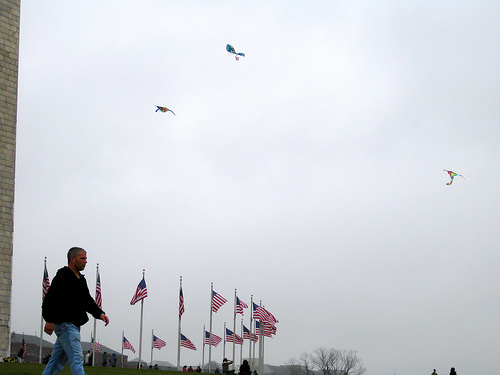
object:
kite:
[223, 42, 245, 62]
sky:
[0, 0, 498, 375]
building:
[0, 2, 17, 364]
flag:
[41, 266, 52, 301]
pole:
[38, 256, 47, 364]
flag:
[123, 274, 149, 306]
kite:
[441, 168, 467, 187]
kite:
[154, 104, 177, 116]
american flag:
[123, 336, 137, 354]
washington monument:
[0, 0, 23, 364]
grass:
[1, 359, 225, 374]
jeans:
[39, 321, 86, 374]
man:
[38, 245, 109, 375]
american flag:
[211, 290, 229, 313]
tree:
[306, 345, 367, 375]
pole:
[177, 276, 183, 371]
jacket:
[40, 266, 106, 327]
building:
[10, 343, 128, 367]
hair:
[66, 246, 86, 264]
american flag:
[129, 279, 148, 306]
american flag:
[178, 290, 186, 317]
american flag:
[252, 302, 271, 320]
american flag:
[152, 335, 166, 350]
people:
[182, 364, 187, 372]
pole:
[135, 269, 146, 370]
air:
[170, 124, 351, 297]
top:
[281, 345, 363, 368]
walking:
[35, 241, 112, 375]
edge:
[11, 342, 37, 347]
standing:
[17, 218, 496, 375]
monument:
[1, 0, 500, 373]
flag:
[94, 272, 102, 308]